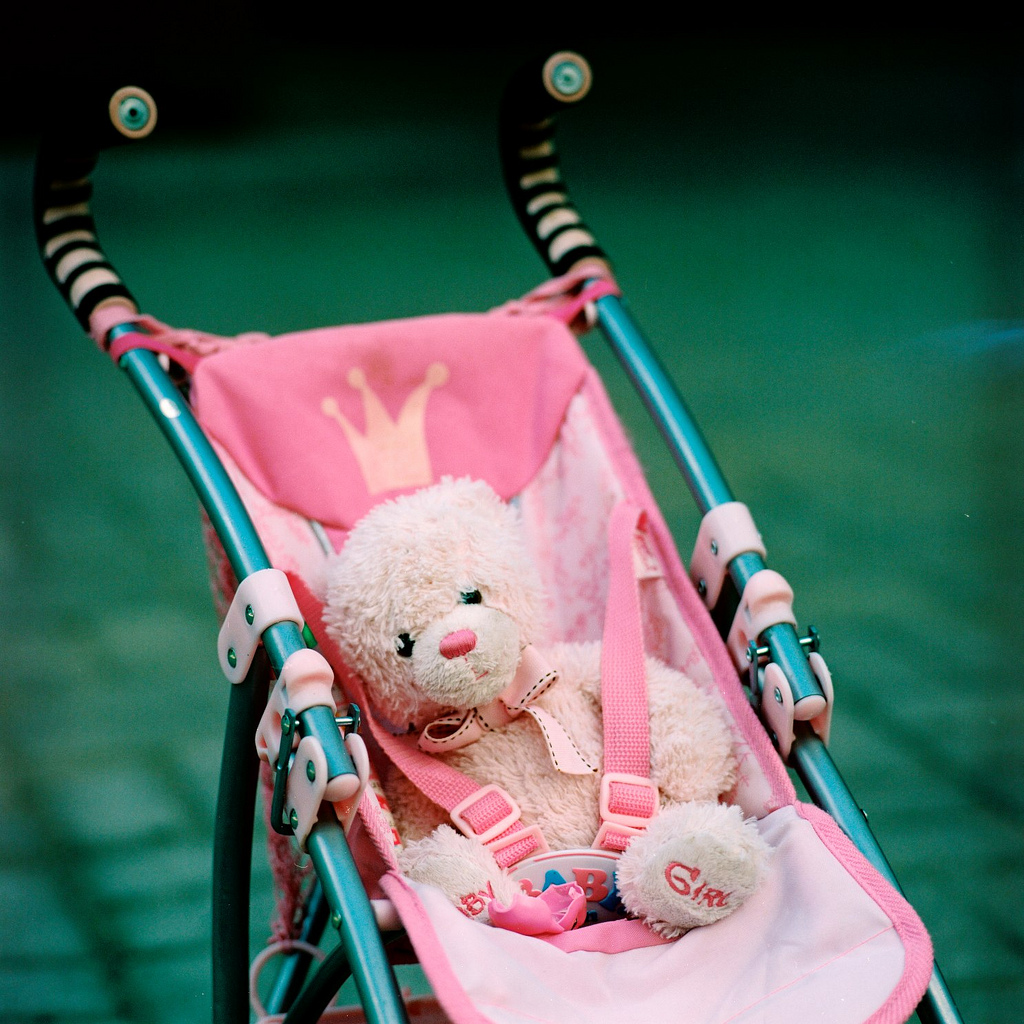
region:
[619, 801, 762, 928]
bottom of bear's sole says "Girl"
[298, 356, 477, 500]
Orange crown pattern on inside of stroller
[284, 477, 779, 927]
Pink teddy bear strapped into stroller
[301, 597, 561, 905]
Pink shoulder strap with plastic buckle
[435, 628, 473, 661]
Pink threaded nose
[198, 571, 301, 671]
Pink plastic clamp on stroller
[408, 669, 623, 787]
Light pink ribbon in a bow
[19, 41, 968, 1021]
Stroller with pink cloth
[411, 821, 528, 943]
Pink teddybear foot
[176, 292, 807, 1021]
Teddy bear in stroller.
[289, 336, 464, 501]
Gold crown on pink fabric.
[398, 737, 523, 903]
Safety straps for stroller.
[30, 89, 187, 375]
Black and pink stroller handles.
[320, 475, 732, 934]
Shaggy pink teddy bear.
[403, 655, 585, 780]
Pink bow with black dots.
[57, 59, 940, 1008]
Stroller for small child.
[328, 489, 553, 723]
Teddy bear with pink nose.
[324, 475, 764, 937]
Wooly pink teddy bear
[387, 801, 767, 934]
"Baby Girl" written on bear's feet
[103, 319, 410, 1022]
green bars on stroller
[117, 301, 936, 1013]
Pink seat on stroller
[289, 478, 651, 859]
Pink straps holding bear in seat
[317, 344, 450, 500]
Orangish pink crown design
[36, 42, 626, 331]
Black handles on stroller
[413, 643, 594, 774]
Little pink bow on teddy bear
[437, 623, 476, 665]
Bright pink nose on teddy bear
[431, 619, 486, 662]
Pink nose on the bear.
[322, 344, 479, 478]
Crown on the back of the stroller.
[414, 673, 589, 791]
Pink ribbon around the bear's neck.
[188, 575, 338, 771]
Side of the stroller with screws.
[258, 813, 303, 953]
Pink fuzzy key chain hanging from the stroller.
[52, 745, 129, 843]
Green squares on the ground.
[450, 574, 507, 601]
Black button as the eye on the bear.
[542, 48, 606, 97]
Circle at the top of the stroller.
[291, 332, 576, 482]
pink crown on a blanket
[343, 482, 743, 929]
soft, pink teddybear with straps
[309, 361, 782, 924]
soft, pink teddy bear with pink crown over its head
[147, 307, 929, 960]
pink stroller with teddy bear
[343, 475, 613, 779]
pink bow on a pink teddy bear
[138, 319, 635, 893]
pink and blue stroller with teddy bear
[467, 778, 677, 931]
the word "baby" on stroller straps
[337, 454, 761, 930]
A toy stuffed animal.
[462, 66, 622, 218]
black handle on pram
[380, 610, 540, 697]
pink nose on bear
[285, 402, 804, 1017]
a teddy bear in a stroller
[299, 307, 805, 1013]
a pink stroller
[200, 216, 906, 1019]
a kids sized stroller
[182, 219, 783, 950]
a pink kid size stroller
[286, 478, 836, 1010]
a bear in a kid size stroller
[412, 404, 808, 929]
pink straps over the bear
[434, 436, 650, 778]
a bear with pink nose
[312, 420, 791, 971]
a light pink bear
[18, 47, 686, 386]
a set of handles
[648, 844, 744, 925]
writing on the paw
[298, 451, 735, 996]
the bear is strapped in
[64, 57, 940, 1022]
bear in a stroller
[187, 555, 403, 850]
pink plastic on stroller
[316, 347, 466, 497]
a light pink crown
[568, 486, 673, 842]
the strap is pink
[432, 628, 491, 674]
pink nose on bear